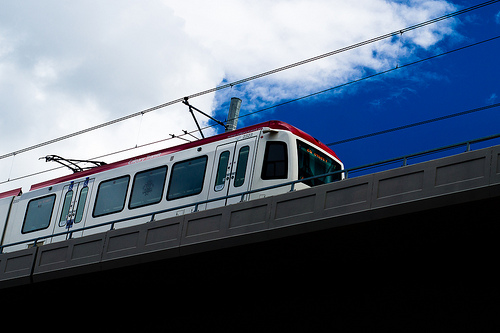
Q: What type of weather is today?
A: It is partly cloudy.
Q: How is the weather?
A: It is partly cloudy.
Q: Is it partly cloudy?
A: Yes, it is partly cloudy.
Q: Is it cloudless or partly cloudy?
A: It is partly cloudy.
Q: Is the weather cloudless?
A: No, it is partly cloudy.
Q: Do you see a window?
A: Yes, there is a window.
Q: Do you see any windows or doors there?
A: Yes, there is a window.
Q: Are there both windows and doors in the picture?
A: Yes, there are both a window and a door.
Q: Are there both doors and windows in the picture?
A: Yes, there are both a window and a door.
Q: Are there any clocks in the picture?
A: No, there are no clocks.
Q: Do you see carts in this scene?
A: No, there are no carts.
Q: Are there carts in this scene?
A: No, there are no carts.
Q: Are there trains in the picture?
A: Yes, there is a train.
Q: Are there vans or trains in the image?
A: Yes, there is a train.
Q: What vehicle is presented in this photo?
A: The vehicle is a train.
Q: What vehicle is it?
A: The vehicle is a train.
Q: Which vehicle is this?
A: This is a train.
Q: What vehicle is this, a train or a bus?
A: This is a train.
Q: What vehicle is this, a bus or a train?
A: This is a train.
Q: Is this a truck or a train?
A: This is a train.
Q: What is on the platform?
A: The train is on the platform.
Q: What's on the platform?
A: The train is on the platform.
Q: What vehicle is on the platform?
A: The vehicle is a train.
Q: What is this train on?
A: The train is on the platform.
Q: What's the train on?
A: The train is on the platform.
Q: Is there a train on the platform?
A: Yes, there is a train on the platform.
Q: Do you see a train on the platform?
A: Yes, there is a train on the platform.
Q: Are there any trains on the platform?
A: Yes, there is a train on the platform.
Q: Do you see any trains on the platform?
A: Yes, there is a train on the platform.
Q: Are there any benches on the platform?
A: No, there is a train on the platform.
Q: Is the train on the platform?
A: Yes, the train is on the platform.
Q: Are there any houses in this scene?
A: No, there are no houses.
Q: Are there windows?
A: Yes, there is a window.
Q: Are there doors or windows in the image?
A: Yes, there is a window.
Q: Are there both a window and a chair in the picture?
A: No, there is a window but no chairs.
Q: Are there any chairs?
A: No, there are no chairs.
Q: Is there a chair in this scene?
A: No, there are no chairs.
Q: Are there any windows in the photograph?
A: Yes, there is a window.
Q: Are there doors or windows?
A: Yes, there is a window.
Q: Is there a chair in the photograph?
A: No, there are no chairs.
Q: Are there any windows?
A: Yes, there is a window.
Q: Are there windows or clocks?
A: Yes, there is a window.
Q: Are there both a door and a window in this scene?
A: Yes, there are both a window and a door.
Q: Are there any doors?
A: Yes, there are doors.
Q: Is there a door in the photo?
A: Yes, there are doors.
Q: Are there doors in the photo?
A: Yes, there are doors.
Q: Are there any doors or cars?
A: Yes, there are doors.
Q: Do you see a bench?
A: No, there are no benches.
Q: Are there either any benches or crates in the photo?
A: No, there are no benches or crates.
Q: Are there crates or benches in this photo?
A: No, there are no benches or crates.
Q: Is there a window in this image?
A: Yes, there is a window.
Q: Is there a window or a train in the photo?
A: Yes, there is a window.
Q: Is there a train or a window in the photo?
A: Yes, there is a window.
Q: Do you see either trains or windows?
A: Yes, there is a window.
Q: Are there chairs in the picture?
A: No, there are no chairs.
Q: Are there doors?
A: Yes, there is a door.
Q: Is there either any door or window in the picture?
A: Yes, there is a door.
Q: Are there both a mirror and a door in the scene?
A: No, there is a door but no mirrors.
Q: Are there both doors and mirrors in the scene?
A: No, there is a door but no mirrors.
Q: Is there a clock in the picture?
A: No, there are no clocks.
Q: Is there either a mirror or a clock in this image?
A: No, there are no clocks or mirrors.